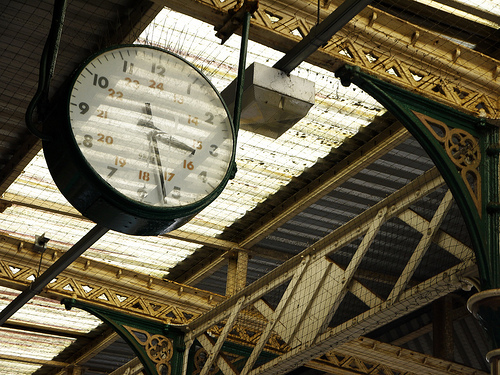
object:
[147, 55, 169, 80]
number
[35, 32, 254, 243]
clock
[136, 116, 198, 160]
hands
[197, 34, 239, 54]
light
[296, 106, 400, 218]
roof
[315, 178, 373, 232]
surface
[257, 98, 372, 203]
sheet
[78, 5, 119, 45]
patch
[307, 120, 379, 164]
decoraction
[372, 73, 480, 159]
rod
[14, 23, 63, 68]
ceiling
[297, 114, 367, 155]
window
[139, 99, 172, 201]
tick